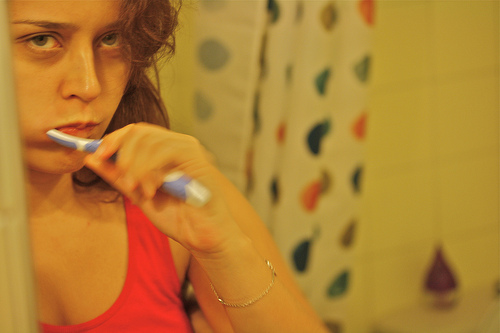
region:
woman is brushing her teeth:
[6, 7, 177, 249]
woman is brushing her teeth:
[6, 3, 154, 279]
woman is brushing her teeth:
[2, 2, 200, 247]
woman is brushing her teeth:
[6, 6, 205, 222]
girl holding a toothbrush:
[31, 113, 258, 240]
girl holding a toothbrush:
[26, 107, 257, 277]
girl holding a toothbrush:
[32, 103, 242, 243]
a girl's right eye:
[17, 29, 67, 56]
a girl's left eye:
[92, 25, 126, 52]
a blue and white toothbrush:
[47, 128, 211, 210]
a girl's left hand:
[82, 122, 243, 252]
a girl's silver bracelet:
[214, 261, 276, 311]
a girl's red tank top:
[40, 199, 190, 331]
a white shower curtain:
[185, 1, 369, 332]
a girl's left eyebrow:
[95, 18, 123, 30]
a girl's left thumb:
[82, 152, 122, 186]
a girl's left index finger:
[94, 121, 135, 159]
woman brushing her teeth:
[6, 4, 326, 329]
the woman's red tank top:
[35, 193, 190, 329]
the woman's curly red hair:
[75, 0, 179, 188]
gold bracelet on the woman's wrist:
[205, 254, 275, 307]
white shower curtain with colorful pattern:
[187, 1, 369, 331]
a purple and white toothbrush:
[48, 129, 208, 204]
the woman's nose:
[64, 36, 99, 104]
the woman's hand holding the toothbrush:
[49, 123, 219, 245]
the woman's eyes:
[27, 33, 122, 49]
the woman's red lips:
[55, 119, 99, 131]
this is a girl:
[51, 94, 346, 331]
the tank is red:
[120, 277, 180, 328]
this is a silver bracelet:
[195, 229, 312, 317]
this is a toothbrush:
[75, 89, 202, 258]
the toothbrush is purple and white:
[80, 97, 173, 203]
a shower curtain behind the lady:
[196, 0, 377, 265]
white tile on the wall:
[383, 13, 498, 205]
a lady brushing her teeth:
[6, 3, 297, 332]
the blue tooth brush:
[47, 120, 212, 204]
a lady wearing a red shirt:
[19, 2, 232, 322]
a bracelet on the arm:
[208, 256, 278, 306]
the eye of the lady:
[15, 28, 69, 55]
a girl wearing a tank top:
[10, 3, 182, 315]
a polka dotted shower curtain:
[211, 3, 366, 235]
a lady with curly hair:
[23, 13, 183, 194]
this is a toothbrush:
[36, 103, 232, 238]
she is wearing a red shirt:
[32, 170, 226, 330]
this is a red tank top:
[23, 150, 220, 329]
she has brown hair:
[9, 1, 211, 253]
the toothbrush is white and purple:
[32, 98, 288, 255]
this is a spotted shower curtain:
[190, 4, 414, 326]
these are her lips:
[50, 106, 112, 152]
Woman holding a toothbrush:
[0, 0, 341, 332]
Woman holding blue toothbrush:
[3, 3, 318, 328]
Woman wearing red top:
[0, 16, 342, 330]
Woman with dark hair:
[1, 18, 329, 330]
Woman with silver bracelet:
[3, 17, 323, 331]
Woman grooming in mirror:
[7, 17, 336, 329]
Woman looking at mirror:
[3, 17, 337, 329]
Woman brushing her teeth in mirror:
[3, 19, 330, 327]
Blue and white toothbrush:
[27, 110, 224, 217]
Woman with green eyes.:
[4, 19, 309, 326]